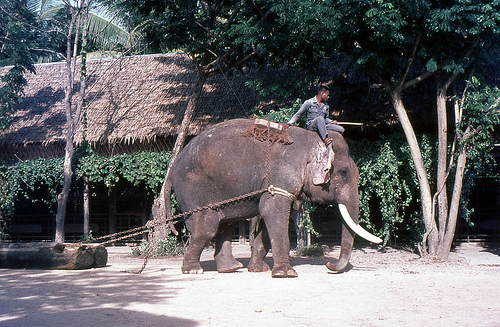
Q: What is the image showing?
A: It is showing a park.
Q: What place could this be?
A: It is a park.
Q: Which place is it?
A: It is a park.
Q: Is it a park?
A: Yes, it is a park.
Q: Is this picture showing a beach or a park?
A: It is showing a park.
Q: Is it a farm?
A: No, it is a park.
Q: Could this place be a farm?
A: No, it is a park.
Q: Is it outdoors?
A: Yes, it is outdoors.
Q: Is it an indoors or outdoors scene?
A: It is outdoors.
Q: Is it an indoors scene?
A: No, it is outdoors.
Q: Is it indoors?
A: No, it is outdoors.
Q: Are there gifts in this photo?
A: No, there are no gifts.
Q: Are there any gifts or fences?
A: No, there are no gifts or fences.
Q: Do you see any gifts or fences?
A: No, there are no gifts or fences.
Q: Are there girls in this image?
A: No, there are no girls.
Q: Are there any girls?
A: No, there are no girls.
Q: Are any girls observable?
A: No, there are no girls.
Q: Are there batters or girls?
A: No, there are no girls or batters.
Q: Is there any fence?
A: No, there are no fences.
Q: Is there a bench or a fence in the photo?
A: No, there are no fences or benches.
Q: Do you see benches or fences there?
A: No, there are no fences or benches.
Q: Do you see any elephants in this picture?
A: Yes, there is an elephant.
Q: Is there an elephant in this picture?
A: Yes, there is an elephant.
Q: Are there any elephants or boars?
A: Yes, there is an elephant.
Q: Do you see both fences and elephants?
A: No, there is an elephant but no fences.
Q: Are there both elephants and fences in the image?
A: No, there is an elephant but no fences.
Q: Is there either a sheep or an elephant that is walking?
A: Yes, the elephant is walking.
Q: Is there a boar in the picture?
A: No, there are no boars.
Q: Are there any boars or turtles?
A: No, there are no boars or turtles.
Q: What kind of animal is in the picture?
A: The animal is an elephant.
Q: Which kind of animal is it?
A: The animal is an elephant.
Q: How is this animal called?
A: This is an elephant.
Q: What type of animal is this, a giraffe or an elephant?
A: This is an elephant.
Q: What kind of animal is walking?
A: The animal is an elephant.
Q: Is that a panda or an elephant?
A: That is an elephant.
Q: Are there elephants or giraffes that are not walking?
A: No, there is an elephant but it is walking.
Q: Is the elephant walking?
A: Yes, the elephant is walking.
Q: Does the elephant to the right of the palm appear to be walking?
A: Yes, the elephant is walking.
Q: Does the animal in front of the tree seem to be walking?
A: Yes, the elephant is walking.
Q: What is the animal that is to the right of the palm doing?
A: The elephant is walking.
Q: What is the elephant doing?
A: The elephant is walking.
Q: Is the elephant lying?
A: No, the elephant is walking.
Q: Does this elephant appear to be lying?
A: No, the elephant is walking.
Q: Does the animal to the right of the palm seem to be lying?
A: No, the elephant is walking.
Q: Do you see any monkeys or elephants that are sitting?
A: No, there is an elephant but it is walking.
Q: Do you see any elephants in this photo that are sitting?
A: No, there is an elephant but it is walking.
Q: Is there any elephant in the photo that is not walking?
A: No, there is an elephant but it is walking.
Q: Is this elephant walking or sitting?
A: The elephant is walking.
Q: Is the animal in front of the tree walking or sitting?
A: The elephant is walking.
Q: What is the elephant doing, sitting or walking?
A: The elephant is walking.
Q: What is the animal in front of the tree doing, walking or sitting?
A: The elephant is walking.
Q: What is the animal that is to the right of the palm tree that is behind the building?
A: The animal is an elephant.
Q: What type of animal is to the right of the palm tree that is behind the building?
A: The animal is an elephant.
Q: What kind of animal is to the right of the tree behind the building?
A: The animal is an elephant.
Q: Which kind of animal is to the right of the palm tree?
A: The animal is an elephant.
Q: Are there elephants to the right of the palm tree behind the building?
A: Yes, there is an elephant to the right of the palm tree.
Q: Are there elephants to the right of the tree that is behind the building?
A: Yes, there is an elephant to the right of the palm tree.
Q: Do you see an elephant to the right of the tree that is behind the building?
A: Yes, there is an elephant to the right of the palm tree.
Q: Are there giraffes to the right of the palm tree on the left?
A: No, there is an elephant to the right of the palm.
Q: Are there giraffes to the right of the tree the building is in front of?
A: No, there is an elephant to the right of the palm.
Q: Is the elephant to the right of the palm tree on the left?
A: Yes, the elephant is to the right of the palm tree.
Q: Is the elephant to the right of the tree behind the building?
A: Yes, the elephant is to the right of the palm tree.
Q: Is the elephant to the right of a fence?
A: No, the elephant is to the right of the palm tree.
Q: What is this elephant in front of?
A: The elephant is in front of the tree.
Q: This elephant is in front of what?
A: The elephant is in front of the tree.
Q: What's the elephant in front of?
A: The elephant is in front of the tree.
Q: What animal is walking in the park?
A: The elephant is walking in the park.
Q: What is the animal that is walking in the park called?
A: The animal is an elephant.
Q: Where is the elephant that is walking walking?
A: The elephant is walking in the park.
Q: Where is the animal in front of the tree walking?
A: The elephant is walking in the park.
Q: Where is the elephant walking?
A: The elephant is walking in the park.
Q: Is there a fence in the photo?
A: No, there are no fences.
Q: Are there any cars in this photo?
A: No, there are no cars.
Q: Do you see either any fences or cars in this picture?
A: No, there are no cars or fences.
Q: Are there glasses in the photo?
A: No, there are no glasses.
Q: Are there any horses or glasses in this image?
A: No, there are no glasses or horses.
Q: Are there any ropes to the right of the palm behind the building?
A: Yes, there is a rope to the right of the palm tree.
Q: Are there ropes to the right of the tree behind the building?
A: Yes, there is a rope to the right of the palm tree.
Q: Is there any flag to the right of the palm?
A: No, there is a rope to the right of the palm.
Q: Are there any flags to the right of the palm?
A: No, there is a rope to the right of the palm.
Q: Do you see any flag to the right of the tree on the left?
A: No, there is a rope to the right of the palm.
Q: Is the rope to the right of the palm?
A: Yes, the rope is to the right of the palm.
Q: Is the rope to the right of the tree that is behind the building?
A: Yes, the rope is to the right of the palm.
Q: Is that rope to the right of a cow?
A: No, the rope is to the right of the palm.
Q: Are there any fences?
A: No, there are no fences.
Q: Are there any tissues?
A: No, there are no tissues.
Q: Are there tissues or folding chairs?
A: No, there are no tissues or folding chairs.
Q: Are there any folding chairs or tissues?
A: No, there are no tissues or folding chairs.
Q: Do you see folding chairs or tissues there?
A: No, there are no tissues or folding chairs.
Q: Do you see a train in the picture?
A: No, there are no trains.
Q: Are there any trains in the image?
A: No, there are no trains.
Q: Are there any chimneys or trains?
A: No, there are no trains or chimneys.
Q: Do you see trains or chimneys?
A: No, there are no trains or chimneys.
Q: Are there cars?
A: No, there are no cars.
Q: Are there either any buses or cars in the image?
A: No, there are no cars or buses.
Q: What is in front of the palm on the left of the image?
A: The building is in front of the palm.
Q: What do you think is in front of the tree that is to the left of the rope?
A: The building is in front of the palm.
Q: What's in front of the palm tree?
A: The building is in front of the palm.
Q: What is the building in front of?
A: The building is in front of the palm tree.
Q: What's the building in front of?
A: The building is in front of the palm tree.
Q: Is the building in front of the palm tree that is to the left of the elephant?
A: Yes, the building is in front of the palm.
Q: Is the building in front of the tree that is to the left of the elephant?
A: Yes, the building is in front of the palm.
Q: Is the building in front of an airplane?
A: No, the building is in front of the palm.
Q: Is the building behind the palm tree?
A: No, the building is in front of the palm tree.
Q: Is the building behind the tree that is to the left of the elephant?
A: No, the building is in front of the palm tree.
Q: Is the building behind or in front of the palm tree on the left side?
A: The building is in front of the palm tree.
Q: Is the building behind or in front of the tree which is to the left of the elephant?
A: The building is in front of the palm tree.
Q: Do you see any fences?
A: No, there are no fences.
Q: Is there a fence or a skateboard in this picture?
A: No, there are no fences or skateboards.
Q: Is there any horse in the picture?
A: No, there are no horses.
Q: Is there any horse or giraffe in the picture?
A: No, there are no horses or giraffes.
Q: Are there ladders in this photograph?
A: No, there are no ladders.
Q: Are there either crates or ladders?
A: No, there are no ladders or crates.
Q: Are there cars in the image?
A: No, there are no cars.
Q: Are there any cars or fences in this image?
A: No, there are no cars or fences.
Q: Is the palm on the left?
A: Yes, the palm is on the left of the image.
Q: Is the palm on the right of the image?
A: No, the palm is on the left of the image.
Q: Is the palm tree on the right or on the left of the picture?
A: The palm tree is on the left of the image.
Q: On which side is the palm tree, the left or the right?
A: The palm tree is on the left of the image.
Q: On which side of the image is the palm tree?
A: The palm tree is on the left of the image.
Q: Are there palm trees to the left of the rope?
A: Yes, there is a palm tree to the left of the rope.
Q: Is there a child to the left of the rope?
A: No, there is a palm tree to the left of the rope.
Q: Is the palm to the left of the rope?
A: Yes, the palm is to the left of the rope.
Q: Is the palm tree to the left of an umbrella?
A: No, the palm tree is to the left of the rope.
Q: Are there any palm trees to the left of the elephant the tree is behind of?
A: Yes, there is a palm tree to the left of the elephant.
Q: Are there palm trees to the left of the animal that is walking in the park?
A: Yes, there is a palm tree to the left of the elephant.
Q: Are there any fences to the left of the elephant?
A: No, there is a palm tree to the left of the elephant.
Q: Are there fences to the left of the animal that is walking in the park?
A: No, there is a palm tree to the left of the elephant.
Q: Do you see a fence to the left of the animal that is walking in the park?
A: No, there is a palm tree to the left of the elephant.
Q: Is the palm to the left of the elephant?
A: Yes, the palm is to the left of the elephant.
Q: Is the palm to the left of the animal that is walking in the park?
A: Yes, the palm is to the left of the elephant.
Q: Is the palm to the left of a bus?
A: No, the palm is to the left of the elephant.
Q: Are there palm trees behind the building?
A: Yes, there is a palm tree behind the building.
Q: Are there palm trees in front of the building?
A: No, the palm tree is behind the building.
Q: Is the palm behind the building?
A: Yes, the palm is behind the building.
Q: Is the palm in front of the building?
A: No, the palm is behind the building.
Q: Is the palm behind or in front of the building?
A: The palm is behind the building.